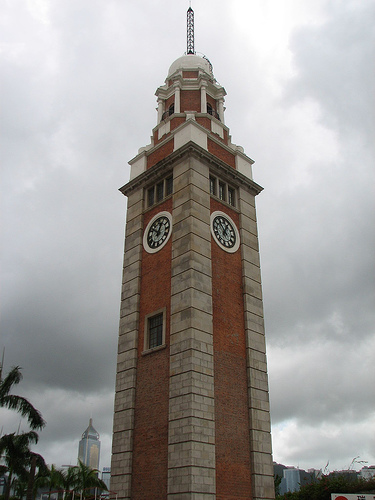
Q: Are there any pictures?
A: No, there are no pictures.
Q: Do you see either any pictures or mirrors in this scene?
A: No, there are no pictures or mirrors.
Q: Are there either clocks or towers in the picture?
A: Yes, there is a clock.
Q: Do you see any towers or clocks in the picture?
A: Yes, there is a clock.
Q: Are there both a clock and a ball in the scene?
A: No, there is a clock but no balls.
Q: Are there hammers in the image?
A: No, there are no hammers.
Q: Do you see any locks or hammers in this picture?
A: No, there are no hammers or locks.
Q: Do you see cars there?
A: No, there are no cars.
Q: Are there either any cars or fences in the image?
A: No, there are no cars or fences.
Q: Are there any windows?
A: Yes, there is a window.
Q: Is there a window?
A: Yes, there is a window.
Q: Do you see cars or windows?
A: Yes, there is a window.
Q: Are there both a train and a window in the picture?
A: No, there is a window but no trains.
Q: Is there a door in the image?
A: No, there are no doors.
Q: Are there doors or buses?
A: No, there are no doors or buses.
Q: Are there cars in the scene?
A: No, there are no cars.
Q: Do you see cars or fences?
A: No, there are no cars or fences.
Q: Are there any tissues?
A: No, there are no tissues.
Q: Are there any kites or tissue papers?
A: No, there are no tissue papers or kites.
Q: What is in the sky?
A: The clouds are in the sky.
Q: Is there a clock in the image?
A: Yes, there is a clock.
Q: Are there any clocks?
A: Yes, there is a clock.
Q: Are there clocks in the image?
A: Yes, there is a clock.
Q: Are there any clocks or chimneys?
A: Yes, there is a clock.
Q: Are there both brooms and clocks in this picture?
A: No, there is a clock but no brooms.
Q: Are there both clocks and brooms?
A: No, there is a clock but no brooms.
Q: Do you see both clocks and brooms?
A: No, there is a clock but no brooms.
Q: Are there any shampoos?
A: No, there are no shampoos.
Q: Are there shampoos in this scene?
A: No, there are no shampoos.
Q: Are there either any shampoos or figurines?
A: No, there are no shampoos or figurines.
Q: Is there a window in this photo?
A: Yes, there is a window.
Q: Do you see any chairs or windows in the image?
A: Yes, there is a window.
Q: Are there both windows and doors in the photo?
A: No, there is a window but no doors.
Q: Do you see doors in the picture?
A: No, there are no doors.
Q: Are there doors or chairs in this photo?
A: No, there are no doors or chairs.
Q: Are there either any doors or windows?
A: Yes, there is a window.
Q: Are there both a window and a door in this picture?
A: No, there is a window but no doors.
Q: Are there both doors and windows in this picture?
A: No, there is a window but no doors.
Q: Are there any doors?
A: No, there are no doors.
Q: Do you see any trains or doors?
A: No, there are no doors or trains.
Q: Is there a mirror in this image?
A: No, there are no mirrors.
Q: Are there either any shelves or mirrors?
A: No, there are no mirrors or shelves.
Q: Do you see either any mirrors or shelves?
A: No, there are no mirrors or shelves.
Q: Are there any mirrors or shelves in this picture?
A: No, there are no mirrors or shelves.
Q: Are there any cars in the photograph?
A: No, there are no cars.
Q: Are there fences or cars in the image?
A: No, there are no cars or fences.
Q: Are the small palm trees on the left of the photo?
A: Yes, the palms are on the left of the image.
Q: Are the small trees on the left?
A: Yes, the palms are on the left of the image.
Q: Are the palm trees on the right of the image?
A: No, the palm trees are on the left of the image.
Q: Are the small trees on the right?
A: No, the palm trees are on the left of the image.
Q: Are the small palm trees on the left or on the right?
A: The palms are on the left of the image.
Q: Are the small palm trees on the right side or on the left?
A: The palms are on the left of the image.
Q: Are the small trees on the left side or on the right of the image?
A: The palms are on the left of the image.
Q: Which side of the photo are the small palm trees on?
A: The palm trees are on the left of the image.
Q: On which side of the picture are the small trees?
A: The palm trees are on the left of the image.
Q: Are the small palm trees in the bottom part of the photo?
A: Yes, the palms are in the bottom of the image.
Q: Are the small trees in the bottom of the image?
A: Yes, the palms are in the bottom of the image.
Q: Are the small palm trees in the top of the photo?
A: No, the palm trees are in the bottom of the image.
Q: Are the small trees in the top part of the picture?
A: No, the palm trees are in the bottom of the image.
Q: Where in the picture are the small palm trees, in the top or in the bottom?
A: The palms are in the bottom of the image.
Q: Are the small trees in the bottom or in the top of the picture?
A: The palms are in the bottom of the image.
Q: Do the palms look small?
A: Yes, the palms are small.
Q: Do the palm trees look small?
A: Yes, the palm trees are small.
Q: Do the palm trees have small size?
A: Yes, the palm trees are small.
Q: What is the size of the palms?
A: The palms are small.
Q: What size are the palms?
A: The palms are small.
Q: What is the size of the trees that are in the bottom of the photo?
A: The palms are small.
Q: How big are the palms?
A: The palms are small.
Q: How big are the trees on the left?
A: The palms are small.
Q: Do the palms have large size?
A: No, the palms are small.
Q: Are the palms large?
A: No, the palms are small.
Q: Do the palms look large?
A: No, the palms are small.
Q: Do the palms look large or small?
A: The palms are small.